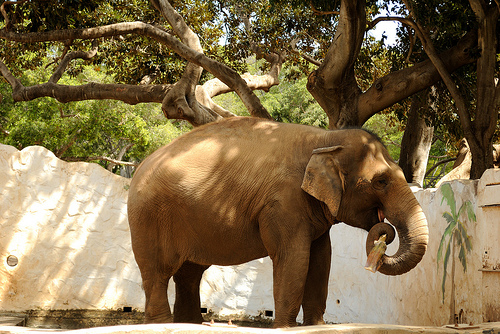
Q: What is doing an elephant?
A: Eaten grass.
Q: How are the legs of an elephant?
A: Shorts.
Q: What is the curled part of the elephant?
A: The trunk.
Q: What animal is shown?
A: Elephant.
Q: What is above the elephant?
A: Tree branches.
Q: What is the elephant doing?
A: Feeding.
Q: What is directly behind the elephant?
A: Stone wall.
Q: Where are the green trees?
A: In the distance.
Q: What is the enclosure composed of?
A: Rock.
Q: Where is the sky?
A: Behind the trees in the foreground.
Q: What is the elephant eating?
A: A branch.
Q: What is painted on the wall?
A: Palm tree.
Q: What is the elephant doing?
A: Eating.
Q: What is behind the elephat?
A: A wall and trees.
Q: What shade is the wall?
A: Light.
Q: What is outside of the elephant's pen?
A: Trees.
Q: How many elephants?
A: One.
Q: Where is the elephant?
A: In a pen.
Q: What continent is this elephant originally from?
A: Asia.